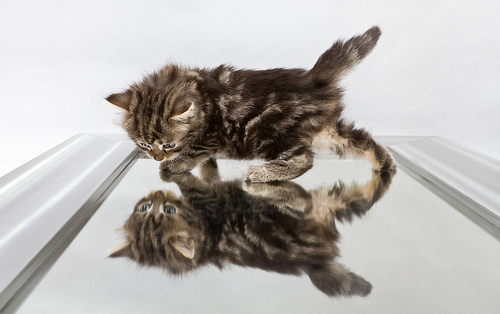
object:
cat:
[100, 26, 398, 297]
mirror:
[4, 144, 499, 313]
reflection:
[105, 170, 401, 301]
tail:
[310, 25, 383, 84]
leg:
[266, 131, 315, 183]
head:
[103, 81, 199, 162]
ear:
[168, 101, 204, 126]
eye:
[163, 141, 176, 149]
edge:
[388, 126, 500, 241]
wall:
[0, 0, 499, 166]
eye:
[138, 140, 153, 150]